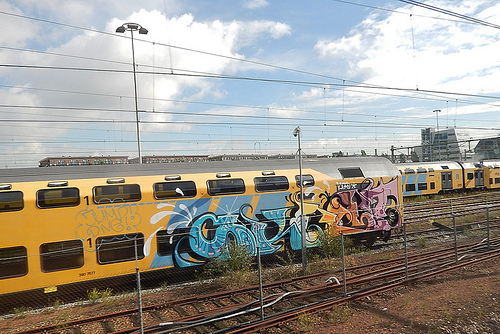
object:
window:
[88, 173, 140, 213]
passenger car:
[486, 162, 499, 187]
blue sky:
[234, 25, 384, 67]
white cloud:
[348, 17, 494, 80]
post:
[255, 244, 266, 322]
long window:
[253, 175, 290, 193]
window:
[144, 180, 198, 198]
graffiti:
[144, 175, 400, 271]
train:
[395, 160, 498, 199]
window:
[417, 182, 428, 190]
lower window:
[0, 245, 30, 279]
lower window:
[38, 238, 85, 272]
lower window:
[94, 231, 143, 264]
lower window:
[156, 228, 195, 257]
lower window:
[417, 182, 427, 190]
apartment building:
[39, 154, 129, 169]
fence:
[0, 211, 497, 334]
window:
[33, 187, 81, 208]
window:
[205, 177, 245, 195]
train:
[0, 153, 404, 310]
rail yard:
[1, 244, 480, 334]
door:
[441, 171, 453, 190]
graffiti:
[76, 195, 143, 253]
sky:
[1, 2, 484, 167]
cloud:
[20, 6, 231, 132]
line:
[153, 290, 311, 332]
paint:
[0, 208, 102, 284]